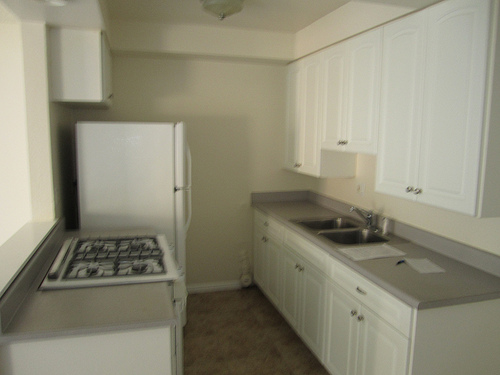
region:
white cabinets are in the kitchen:
[7, 7, 498, 372]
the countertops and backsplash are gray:
[8, 190, 498, 333]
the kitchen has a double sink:
[287, 200, 394, 251]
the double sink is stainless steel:
[288, 211, 388, 247]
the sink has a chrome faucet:
[346, 204, 381, 234]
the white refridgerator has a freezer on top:
[71, 118, 193, 330]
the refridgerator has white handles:
[170, 135, 197, 245]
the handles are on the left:
[174, 135, 199, 238]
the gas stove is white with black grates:
[45, 229, 192, 372]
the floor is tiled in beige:
[181, 278, 333, 373]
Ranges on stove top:
[65, 230, 167, 280]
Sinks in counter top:
[295, 212, 386, 255]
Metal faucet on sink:
[343, 201, 380, 232]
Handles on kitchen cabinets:
[289, 259, 306, 278]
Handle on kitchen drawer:
[348, 280, 373, 301]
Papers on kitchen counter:
[333, 234, 445, 286]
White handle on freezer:
[182, 144, 197, 188]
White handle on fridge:
[180, 189, 198, 232]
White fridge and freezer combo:
[70, 117, 197, 289]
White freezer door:
[170, 114, 185, 191]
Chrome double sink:
[295, 204, 388, 249]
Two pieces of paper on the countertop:
[340, 237, 442, 279]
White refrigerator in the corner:
[71, 116, 193, 328]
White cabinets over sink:
[317, 34, 377, 156]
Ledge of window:
[0, 212, 55, 280]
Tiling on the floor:
[183, 288, 327, 371]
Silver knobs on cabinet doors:
[343, 303, 371, 324]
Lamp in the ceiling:
[193, 0, 248, 19]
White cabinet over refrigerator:
[46, 27, 118, 105]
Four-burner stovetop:
[60, 232, 163, 286]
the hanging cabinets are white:
[275, 0, 491, 216]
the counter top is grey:
[241, 180, 498, 312]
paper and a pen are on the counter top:
[387, 254, 447, 279]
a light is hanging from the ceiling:
[205, 3, 250, 22]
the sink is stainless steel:
[282, 216, 388, 252]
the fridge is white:
[72, 119, 187, 308]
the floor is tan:
[177, 282, 332, 373]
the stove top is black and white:
[45, 228, 175, 283]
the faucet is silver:
[347, 202, 375, 232]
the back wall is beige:
[60, 40, 310, 297]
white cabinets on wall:
[280, 6, 492, 216]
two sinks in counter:
[303, 214, 383, 250]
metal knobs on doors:
[400, 179, 426, 198]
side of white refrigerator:
[81, 122, 192, 236]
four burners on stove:
[58, 231, 172, 289]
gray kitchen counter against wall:
[261, 194, 498, 316]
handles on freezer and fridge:
[178, 144, 196, 236]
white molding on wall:
[183, 279, 250, 295]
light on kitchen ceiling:
[200, 0, 245, 23]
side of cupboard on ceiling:
[47, 26, 119, 111]